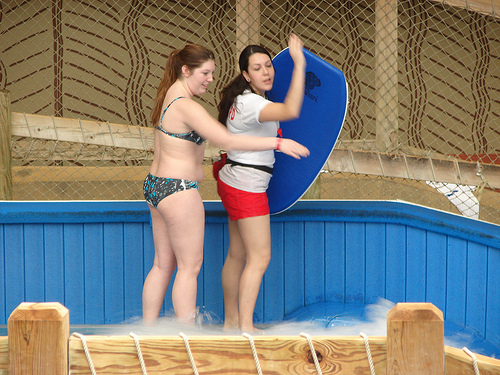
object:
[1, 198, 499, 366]
sides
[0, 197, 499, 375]
wading pool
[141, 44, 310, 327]
woman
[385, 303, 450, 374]
posts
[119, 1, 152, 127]
lines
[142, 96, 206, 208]
bathing suit